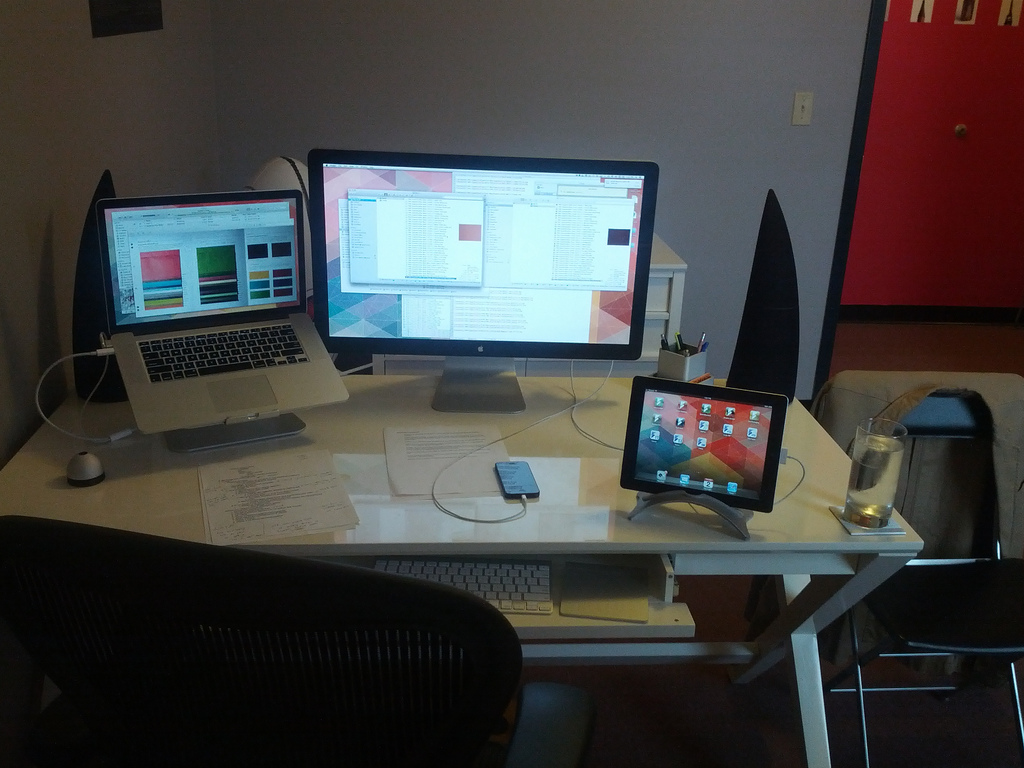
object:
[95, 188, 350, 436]
laptop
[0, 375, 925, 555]
desk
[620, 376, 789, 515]
tablet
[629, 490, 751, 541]
stand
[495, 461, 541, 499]
phone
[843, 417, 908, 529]
glass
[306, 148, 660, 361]
monitor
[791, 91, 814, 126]
switch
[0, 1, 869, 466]
wall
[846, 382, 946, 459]
jacket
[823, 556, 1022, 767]
chair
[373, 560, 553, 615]
keyboard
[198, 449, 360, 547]
papers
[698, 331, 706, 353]
pens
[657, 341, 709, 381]
container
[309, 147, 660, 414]
computer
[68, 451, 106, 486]
mouse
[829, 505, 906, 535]
coaster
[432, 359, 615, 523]
cable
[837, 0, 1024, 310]
door